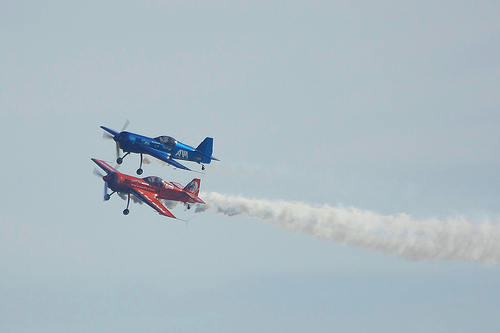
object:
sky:
[398, 122, 453, 155]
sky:
[459, 148, 492, 167]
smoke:
[366, 216, 478, 256]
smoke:
[199, 182, 345, 257]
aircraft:
[80, 148, 206, 228]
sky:
[354, 282, 439, 321]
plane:
[90, 155, 205, 218]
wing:
[133, 187, 183, 220]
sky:
[346, 0, 498, 86]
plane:
[96, 119, 221, 175]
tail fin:
[184, 174, 202, 199]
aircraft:
[97, 113, 224, 176]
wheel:
[123, 207, 130, 216]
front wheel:
[103, 190, 111, 202]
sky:
[0, 0, 77, 32]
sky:
[228, 246, 304, 313]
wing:
[155, 151, 192, 171]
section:
[270, 219, 342, 260]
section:
[298, 267, 395, 305]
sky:
[309, 256, 342, 286]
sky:
[11, 98, 62, 124]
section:
[10, 0, 85, 95]